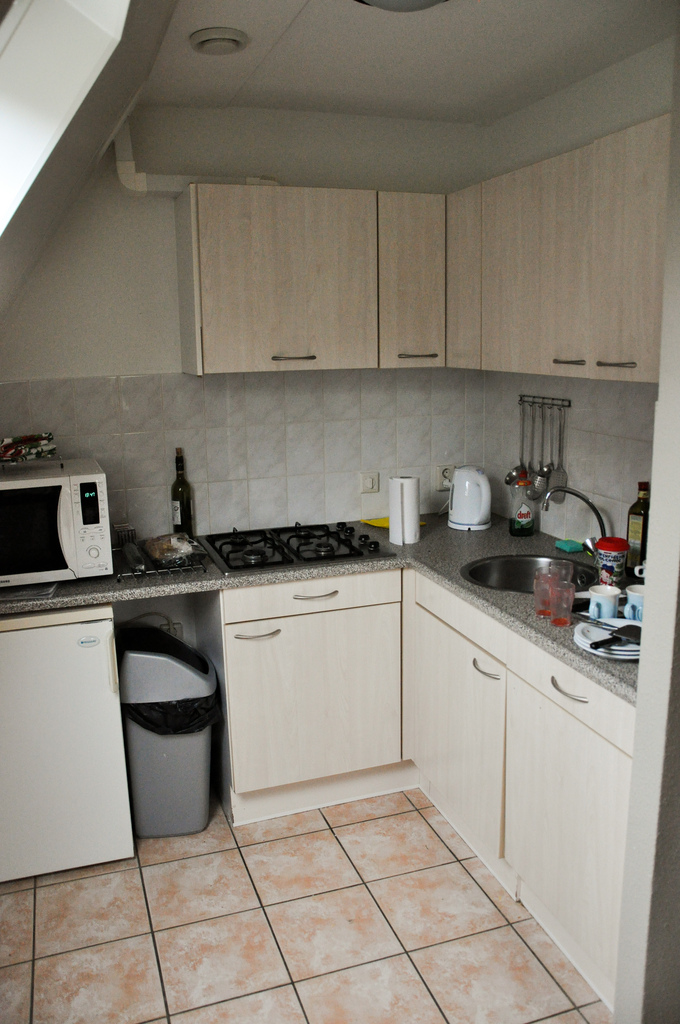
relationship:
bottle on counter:
[170, 446, 194, 539] [0, 511, 636, 705]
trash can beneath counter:
[115, 618, 222, 839] [0, 511, 636, 705]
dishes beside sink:
[538, 537, 644, 667] [464, 552, 598, 593]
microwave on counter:
[1, 457, 115, 588] [0, 511, 636, 705]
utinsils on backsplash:
[502, 387, 571, 507] [0, 378, 659, 553]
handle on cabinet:
[273, 354, 317, 367] [198, 185, 383, 372]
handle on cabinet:
[400, 349, 446, 359] [378, 185, 447, 371]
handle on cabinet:
[547, 354, 588, 372] [480, 140, 593, 377]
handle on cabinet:
[594, 359, 633, 373] [591, 114, 677, 383]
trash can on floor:
[115, 618, 222, 839] [2, 789, 613, 1021]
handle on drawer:
[294, 586, 345, 607] [225, 569, 405, 627]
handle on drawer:
[543, 669, 587, 708] [407, 569, 638, 761]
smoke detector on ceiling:
[181, 24, 253, 61] [2, 2, 677, 123]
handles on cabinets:
[270, 349, 639, 377] [166, 107, 676, 377]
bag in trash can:
[129, 675, 219, 734] [115, 618, 222, 839]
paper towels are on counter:
[388, 475, 419, 545] [0, 511, 636, 705]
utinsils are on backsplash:
[502, 387, 571, 507] [0, 378, 659, 553]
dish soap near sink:
[508, 475, 540, 534] [464, 552, 598, 593]